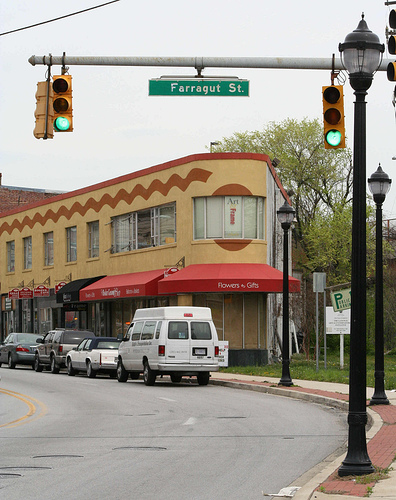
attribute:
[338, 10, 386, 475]
light post — large, black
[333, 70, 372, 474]
pole — black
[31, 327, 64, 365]
car — parked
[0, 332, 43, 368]
car — parked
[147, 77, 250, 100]
signs — yellow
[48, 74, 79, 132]
light — green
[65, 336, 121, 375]
car — white , blue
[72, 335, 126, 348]
top — blue 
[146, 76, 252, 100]
sign — green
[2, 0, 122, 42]
powerline — hanging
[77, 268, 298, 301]
awnings — red 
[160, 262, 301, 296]
awning — Red 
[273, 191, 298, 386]
light post — black, large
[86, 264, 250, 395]
car — white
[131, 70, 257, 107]
sign — white 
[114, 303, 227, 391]
car — parked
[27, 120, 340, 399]
building — white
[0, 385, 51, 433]
yellow lines — painted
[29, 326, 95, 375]
suv — silver 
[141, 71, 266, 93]
sign — hanging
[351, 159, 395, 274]
light post — large, black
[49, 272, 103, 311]
awning — Black 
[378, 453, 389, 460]
brick — red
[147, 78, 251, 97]
sign — white, green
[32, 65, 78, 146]
traffic lights — hanging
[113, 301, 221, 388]
van — parked, white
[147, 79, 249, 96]
sign — green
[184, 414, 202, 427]
line — white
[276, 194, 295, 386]
street lamp — Tall , black 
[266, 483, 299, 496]
paper — lying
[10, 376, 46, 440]
line — yellow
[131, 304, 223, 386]
van — white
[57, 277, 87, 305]
canopy — black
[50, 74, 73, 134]
traffic light — green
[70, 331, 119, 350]
roof — blue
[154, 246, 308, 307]
sign — red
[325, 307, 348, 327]
lettering — white